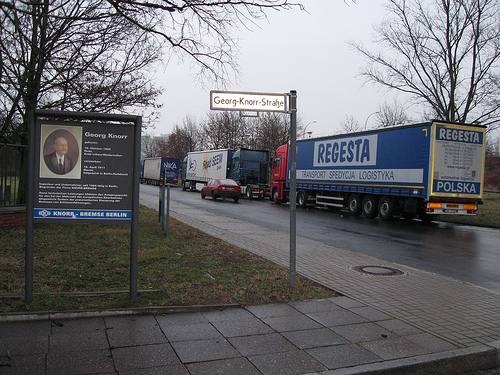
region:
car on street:
[198, 178, 245, 201]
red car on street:
[201, 179, 238, 199]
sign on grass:
[26, 112, 146, 304]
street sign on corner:
[211, 90, 288, 110]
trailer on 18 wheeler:
[293, 118, 480, 216]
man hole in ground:
[357, 264, 407, 277]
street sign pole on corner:
[289, 92, 295, 295]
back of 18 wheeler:
[432, 124, 482, 197]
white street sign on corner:
[213, 92, 287, 107]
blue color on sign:
[36, 209, 133, 219]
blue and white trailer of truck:
[283, 122, 482, 209]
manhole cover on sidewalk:
[353, 257, 394, 281]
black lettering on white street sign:
[207, 89, 285, 114]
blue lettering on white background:
[310, 141, 375, 162]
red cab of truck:
[268, 142, 290, 203]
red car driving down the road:
[197, 177, 237, 199]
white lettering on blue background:
[435, 124, 481, 146]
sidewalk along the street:
[18, 178, 498, 371]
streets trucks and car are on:
[148, 172, 498, 302]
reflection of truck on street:
[381, 205, 481, 267]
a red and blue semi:
[266, 124, 490, 202]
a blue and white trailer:
[291, 126, 482, 196]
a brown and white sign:
[20, 107, 150, 312]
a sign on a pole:
[210, 92, 296, 286]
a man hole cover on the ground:
[364, 261, 400, 287]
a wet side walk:
[88, 306, 424, 370]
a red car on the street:
[197, 178, 246, 199]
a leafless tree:
[362, 2, 499, 113]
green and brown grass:
[154, 224, 239, 292]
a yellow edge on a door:
[431, 122, 489, 200]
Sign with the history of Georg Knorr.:
[22, 103, 145, 306]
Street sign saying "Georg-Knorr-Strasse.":
[207, 84, 301, 284]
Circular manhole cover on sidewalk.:
[351, 259, 408, 279]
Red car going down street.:
[198, 175, 242, 204]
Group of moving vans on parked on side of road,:
[140, 118, 490, 223]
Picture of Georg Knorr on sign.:
[39, 122, 81, 180]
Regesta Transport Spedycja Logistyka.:
[297, 135, 397, 184]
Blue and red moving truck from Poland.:
[269, 115, 491, 223]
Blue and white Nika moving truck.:
[139, 156, 180, 188]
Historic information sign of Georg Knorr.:
[20, 105, 144, 313]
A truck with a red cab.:
[267, 119, 487, 227]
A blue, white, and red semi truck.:
[266, 119, 487, 225]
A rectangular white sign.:
[207, 89, 292, 114]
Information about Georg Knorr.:
[35, 119, 137, 221]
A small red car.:
[199, 177, 244, 204]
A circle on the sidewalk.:
[350, 259, 406, 284]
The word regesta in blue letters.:
[312, 138, 371, 165]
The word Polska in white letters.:
[435, 180, 478, 196]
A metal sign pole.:
[285, 89, 302, 290]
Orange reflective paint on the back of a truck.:
[427, 201, 477, 213]